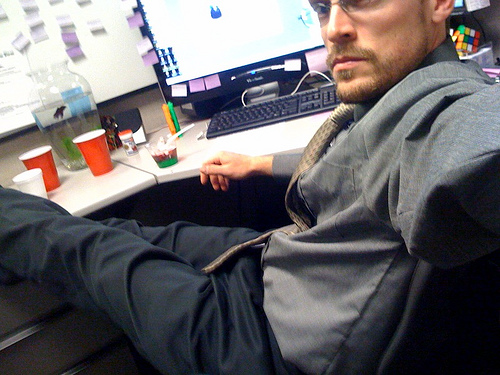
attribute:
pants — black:
[55, 196, 209, 301]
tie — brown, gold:
[304, 106, 365, 187]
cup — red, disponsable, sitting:
[62, 113, 122, 163]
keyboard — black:
[204, 97, 331, 135]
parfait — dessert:
[141, 122, 179, 173]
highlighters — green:
[170, 94, 196, 120]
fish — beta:
[50, 101, 136, 158]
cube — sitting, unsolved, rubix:
[449, 21, 479, 58]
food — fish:
[118, 127, 151, 136]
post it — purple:
[179, 76, 216, 89]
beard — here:
[329, 60, 386, 104]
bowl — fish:
[27, 71, 146, 186]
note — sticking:
[134, 23, 254, 102]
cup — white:
[20, 168, 65, 198]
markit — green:
[163, 97, 192, 124]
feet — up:
[6, 170, 90, 323]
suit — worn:
[286, 101, 435, 317]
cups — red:
[23, 138, 121, 180]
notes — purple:
[127, 24, 245, 139]